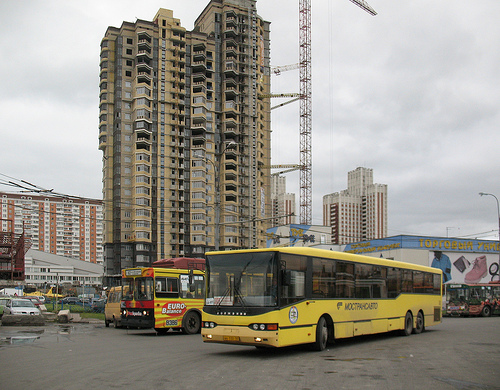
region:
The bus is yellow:
[198, 242, 447, 354]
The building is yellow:
[96, 1, 266, 276]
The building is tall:
[99, 2, 269, 255]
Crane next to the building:
[271, 4, 315, 240]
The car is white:
[4, 294, 42, 324]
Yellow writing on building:
[343, 237, 495, 256]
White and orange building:
[3, 190, 103, 267]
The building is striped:
[1, 189, 105, 261]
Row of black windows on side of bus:
[211, 252, 441, 321]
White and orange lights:
[201, 318, 274, 335]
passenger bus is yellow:
[195, 235, 454, 359]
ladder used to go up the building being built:
[287, 5, 338, 239]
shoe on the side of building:
[459, 254, 498, 293]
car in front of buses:
[7, 291, 57, 341]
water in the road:
[11, 315, 93, 358]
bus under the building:
[442, 275, 495, 317]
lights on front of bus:
[199, 312, 280, 350]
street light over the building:
[470, 186, 496, 239]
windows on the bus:
[202, 253, 445, 307]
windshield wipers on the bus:
[202, 280, 275, 319]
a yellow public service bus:
[200, 245, 444, 351]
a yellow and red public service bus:
[118, 265, 205, 337]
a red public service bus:
[445, 281, 498, 316]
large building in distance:
[100, 0, 270, 282]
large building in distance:
[323, 165, 388, 242]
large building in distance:
[271, 171, 296, 223]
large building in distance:
[0, 194, 102, 266]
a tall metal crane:
[297, 0, 379, 222]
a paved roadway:
[0, 313, 497, 388]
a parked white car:
[2, 296, 40, 316]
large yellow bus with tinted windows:
[202, 246, 459, 353]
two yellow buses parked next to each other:
[116, 247, 450, 357]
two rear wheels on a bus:
[396, 303, 433, 342]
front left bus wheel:
[303, 307, 353, 359]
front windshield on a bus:
[206, 251, 279, 313]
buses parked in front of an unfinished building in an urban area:
[0, 2, 499, 389]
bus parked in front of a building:
[443, 228, 498, 330]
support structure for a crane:
[291, 0, 326, 225]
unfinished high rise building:
[99, 0, 276, 248]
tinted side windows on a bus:
[279, 251, 447, 304]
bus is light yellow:
[175, 220, 465, 365]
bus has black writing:
[330, 298, 393, 333]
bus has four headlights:
[197, 315, 279, 332]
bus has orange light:
[260, 318, 279, 334]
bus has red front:
[112, 260, 166, 332]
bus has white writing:
[141, 290, 188, 328]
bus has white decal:
[275, 300, 307, 328]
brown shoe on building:
[459, 247, 495, 294]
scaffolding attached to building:
[227, 1, 344, 250]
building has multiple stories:
[76, 4, 303, 261]